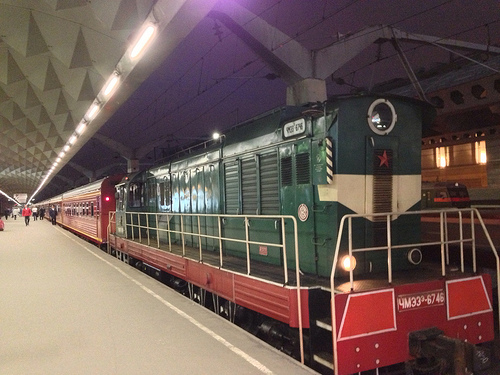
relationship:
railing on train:
[110, 208, 494, 287] [27, 91, 499, 374]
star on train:
[373, 144, 396, 173] [27, 91, 499, 374]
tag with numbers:
[395, 289, 445, 311] [410, 287, 445, 309]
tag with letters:
[395, 289, 445, 311] [398, 295, 411, 311]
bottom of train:
[108, 229, 493, 370] [104, 89, 499, 373]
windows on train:
[59, 200, 101, 217] [27, 91, 499, 374]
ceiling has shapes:
[5, 5, 157, 224] [3, 3, 138, 223]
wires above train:
[91, 0, 498, 177] [27, 91, 499, 374]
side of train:
[143, 106, 338, 277] [27, 91, 499, 374]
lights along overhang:
[23, 20, 158, 204] [26, 12, 168, 161]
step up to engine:
[307, 339, 339, 369] [110, 86, 491, 374]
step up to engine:
[310, 287, 334, 370] [110, 86, 491, 374]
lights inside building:
[38, 25, 171, 204] [5, 2, 482, 371]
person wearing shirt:
[20, 205, 32, 221] [22, 200, 29, 211]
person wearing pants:
[50, 203, 57, 225] [22, 216, 29, 223]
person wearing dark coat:
[50, 203, 58, 221] [11, 178, 74, 249]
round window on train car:
[363, 100, 397, 130] [24, 90, 499, 375]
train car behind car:
[61, 173, 125, 244] [113, 100, 425, 268]